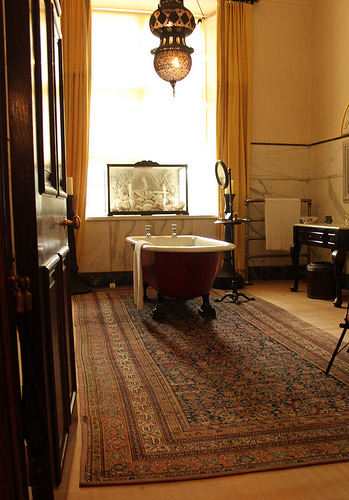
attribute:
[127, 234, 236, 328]
bathtub — red, white, freestanding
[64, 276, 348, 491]
floor — brown, wood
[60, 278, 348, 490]
rug — large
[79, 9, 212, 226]
window — large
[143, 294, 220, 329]
feet — claw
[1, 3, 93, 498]
door — wood, brown, open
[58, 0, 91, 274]
curtain — yellow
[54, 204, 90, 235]
door knob — brass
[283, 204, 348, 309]
table — dark brown, wooden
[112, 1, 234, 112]
chandelier — hanging